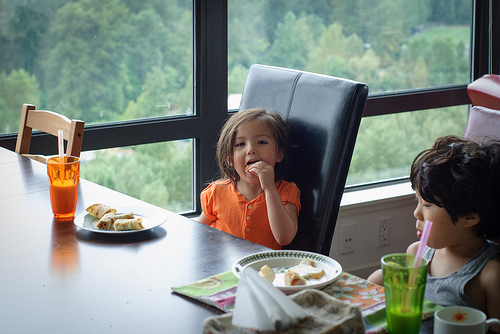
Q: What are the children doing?
A: Eating.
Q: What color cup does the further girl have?
A: Orange.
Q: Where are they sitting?
A: At the table.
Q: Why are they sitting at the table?
A: To eat.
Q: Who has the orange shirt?
A: The further girl.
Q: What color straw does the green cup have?
A: Pink.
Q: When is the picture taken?
A: Daytime.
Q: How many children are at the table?
A: Two.